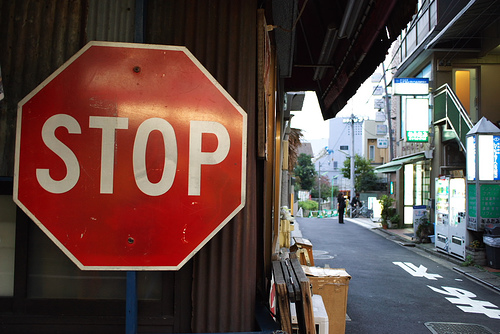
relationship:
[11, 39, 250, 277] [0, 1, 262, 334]
sign against wall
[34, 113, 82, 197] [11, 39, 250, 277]
s on top of sign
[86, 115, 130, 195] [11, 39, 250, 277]
t on top of sign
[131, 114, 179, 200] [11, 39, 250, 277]
o on top of sign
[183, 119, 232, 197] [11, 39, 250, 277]
p on top of sign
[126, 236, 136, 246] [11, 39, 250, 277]
screw inside sign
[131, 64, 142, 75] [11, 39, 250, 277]
screw inside sign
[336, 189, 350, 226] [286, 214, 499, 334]
person standing on pavement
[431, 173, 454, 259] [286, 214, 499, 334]
vending machine on top of pavement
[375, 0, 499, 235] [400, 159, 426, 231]
building has light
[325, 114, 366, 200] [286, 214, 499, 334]
building at end of pavement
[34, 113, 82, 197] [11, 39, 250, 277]
s written on sign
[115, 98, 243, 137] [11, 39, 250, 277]
reflection cast onto sign